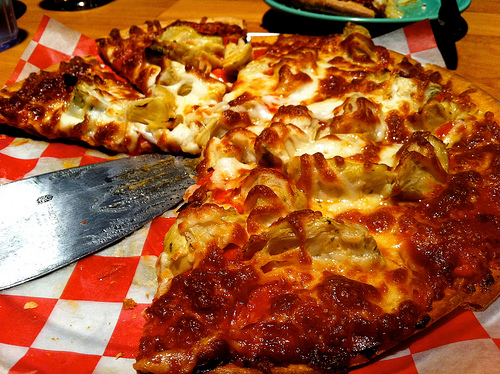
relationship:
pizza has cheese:
[44, 26, 476, 369] [184, 40, 288, 126]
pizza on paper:
[44, 26, 476, 369] [14, 132, 144, 347]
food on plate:
[332, 1, 419, 12] [263, 1, 455, 17]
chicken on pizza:
[129, 96, 238, 152] [44, 26, 476, 369]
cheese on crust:
[184, 40, 288, 126] [116, 19, 259, 53]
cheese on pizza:
[184, 40, 288, 126] [44, 26, 476, 369]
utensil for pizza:
[4, 154, 196, 271] [44, 26, 476, 369]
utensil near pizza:
[4, 154, 196, 271] [44, 26, 476, 369]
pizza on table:
[44, 26, 476, 369] [443, 5, 492, 73]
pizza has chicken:
[44, 26, 476, 369] [129, 96, 238, 152]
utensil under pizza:
[4, 154, 196, 271] [44, 26, 476, 369]